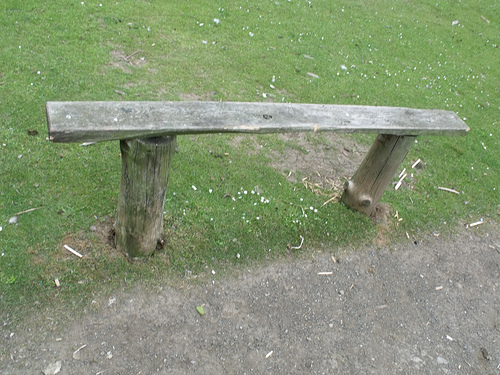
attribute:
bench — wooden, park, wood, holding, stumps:
[30, 55, 480, 178]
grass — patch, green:
[208, 12, 341, 86]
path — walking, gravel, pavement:
[70, 244, 471, 360]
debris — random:
[187, 22, 367, 87]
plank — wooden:
[38, 38, 464, 201]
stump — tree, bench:
[110, 122, 194, 273]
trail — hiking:
[316, 249, 479, 348]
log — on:
[27, 76, 187, 186]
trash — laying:
[56, 232, 93, 283]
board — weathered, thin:
[33, 62, 467, 176]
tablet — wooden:
[2, 36, 463, 264]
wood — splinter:
[112, 221, 191, 283]